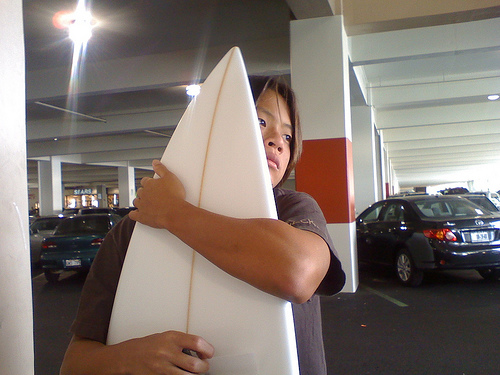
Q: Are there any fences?
A: No, there are no fences.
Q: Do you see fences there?
A: No, there are no fences.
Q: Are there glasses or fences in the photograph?
A: No, there are no fences or glasses.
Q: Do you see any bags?
A: No, there are no bags.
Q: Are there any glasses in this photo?
A: No, there are no glasses.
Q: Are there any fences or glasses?
A: No, there are no glasses or fences.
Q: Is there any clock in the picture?
A: No, there are no clocks.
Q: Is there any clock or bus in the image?
A: No, there are no clocks or buses.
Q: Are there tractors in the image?
A: No, there are no tractors.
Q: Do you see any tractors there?
A: No, there are no tractors.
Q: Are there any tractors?
A: No, there are no tractors.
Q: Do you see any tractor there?
A: No, there are no tractors.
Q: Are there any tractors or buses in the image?
A: No, there are no tractors or buses.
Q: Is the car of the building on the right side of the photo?
A: Yes, the car is on the right of the image.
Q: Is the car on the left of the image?
A: No, the car is on the right of the image.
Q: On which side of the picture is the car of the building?
A: The car is on the right of the image.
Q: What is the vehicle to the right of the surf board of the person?
A: The vehicle is a car.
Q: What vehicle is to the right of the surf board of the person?
A: The vehicle is a car.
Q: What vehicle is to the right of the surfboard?
A: The vehicle is a car.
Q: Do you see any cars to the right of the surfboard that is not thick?
A: Yes, there is a car to the right of the surfboard.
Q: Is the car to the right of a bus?
A: No, the car is to the right of the surfboard.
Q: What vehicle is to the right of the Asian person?
A: The vehicle is a car.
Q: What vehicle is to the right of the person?
A: The vehicle is a car.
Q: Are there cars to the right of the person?
A: Yes, there is a car to the right of the person.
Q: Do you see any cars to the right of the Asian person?
A: Yes, there is a car to the right of the person.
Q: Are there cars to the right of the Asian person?
A: Yes, there is a car to the right of the person.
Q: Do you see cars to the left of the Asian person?
A: No, the car is to the right of the person.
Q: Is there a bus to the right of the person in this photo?
A: No, there is a car to the right of the person.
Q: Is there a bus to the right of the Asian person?
A: No, there is a car to the right of the person.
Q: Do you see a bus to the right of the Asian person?
A: No, there is a car to the right of the person.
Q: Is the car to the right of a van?
A: No, the car is to the right of the person.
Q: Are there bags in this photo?
A: No, there are no bags.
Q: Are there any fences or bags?
A: No, there are no bags or fences.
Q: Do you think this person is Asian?
A: Yes, the person is asian.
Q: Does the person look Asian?
A: Yes, the person is asian.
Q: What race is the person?
A: The person is asian.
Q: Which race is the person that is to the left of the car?
A: The person is asian.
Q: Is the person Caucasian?
A: No, the person is asian.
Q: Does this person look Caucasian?
A: No, the person is asian.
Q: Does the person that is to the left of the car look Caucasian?
A: No, the person is asian.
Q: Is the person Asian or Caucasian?
A: The person is asian.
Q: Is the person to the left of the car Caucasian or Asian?
A: The person is asian.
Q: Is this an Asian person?
A: Yes, this is an Asian person.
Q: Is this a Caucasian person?
A: No, this is an Asian person.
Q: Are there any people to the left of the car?
A: Yes, there is a person to the left of the car.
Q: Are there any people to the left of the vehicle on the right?
A: Yes, there is a person to the left of the car.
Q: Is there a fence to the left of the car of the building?
A: No, there is a person to the left of the car.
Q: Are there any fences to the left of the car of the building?
A: No, there is a person to the left of the car.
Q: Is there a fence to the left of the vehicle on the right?
A: No, there is a person to the left of the car.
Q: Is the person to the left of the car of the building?
A: Yes, the person is to the left of the car.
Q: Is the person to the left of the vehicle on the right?
A: Yes, the person is to the left of the car.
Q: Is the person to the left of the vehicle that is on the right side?
A: Yes, the person is to the left of the car.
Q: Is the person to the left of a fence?
A: No, the person is to the left of the car.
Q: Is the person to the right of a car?
A: No, the person is to the left of a car.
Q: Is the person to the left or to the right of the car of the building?
A: The person is to the left of the car.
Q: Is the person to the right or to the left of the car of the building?
A: The person is to the left of the car.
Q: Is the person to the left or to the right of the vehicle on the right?
A: The person is to the left of the car.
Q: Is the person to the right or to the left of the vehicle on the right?
A: The person is to the left of the car.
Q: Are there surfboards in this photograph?
A: Yes, there is a surfboard.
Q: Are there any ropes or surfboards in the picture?
A: Yes, there is a surfboard.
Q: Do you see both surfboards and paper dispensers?
A: No, there is a surfboard but no paper dispensers.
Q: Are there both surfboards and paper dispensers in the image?
A: No, there is a surfboard but no paper dispensers.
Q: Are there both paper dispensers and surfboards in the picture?
A: No, there is a surfboard but no paper dispensers.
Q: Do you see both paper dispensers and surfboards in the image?
A: No, there is a surfboard but no paper dispensers.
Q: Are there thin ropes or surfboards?
A: Yes, there is a thin surfboard.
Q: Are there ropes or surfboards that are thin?
A: Yes, the surfboard is thin.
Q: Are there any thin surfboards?
A: Yes, there is a thin surfboard.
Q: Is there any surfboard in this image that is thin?
A: Yes, there is a surfboard that is thin.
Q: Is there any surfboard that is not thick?
A: Yes, there is a thin surfboard.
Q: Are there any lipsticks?
A: No, there are no lipsticks.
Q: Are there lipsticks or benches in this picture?
A: No, there are no lipsticks or benches.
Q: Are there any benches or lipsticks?
A: No, there are no lipsticks or benches.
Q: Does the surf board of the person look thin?
A: Yes, the surfboard is thin.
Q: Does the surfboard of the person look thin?
A: Yes, the surfboard is thin.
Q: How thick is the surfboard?
A: The surfboard is thin.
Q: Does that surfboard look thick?
A: No, the surfboard is thin.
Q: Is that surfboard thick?
A: No, the surfboard is thin.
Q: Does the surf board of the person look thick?
A: No, the surfboard is thin.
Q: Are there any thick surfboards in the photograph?
A: No, there is a surfboard but it is thin.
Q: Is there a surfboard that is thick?
A: No, there is a surfboard but it is thin.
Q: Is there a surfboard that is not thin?
A: No, there is a surfboard but it is thin.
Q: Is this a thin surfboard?
A: Yes, this is a thin surfboard.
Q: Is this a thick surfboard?
A: No, this is a thin surfboard.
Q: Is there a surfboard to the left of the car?
A: Yes, there is a surfboard to the left of the car.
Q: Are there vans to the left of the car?
A: No, there is a surfboard to the left of the car.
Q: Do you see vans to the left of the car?
A: No, there is a surfboard to the left of the car.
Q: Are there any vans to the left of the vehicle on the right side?
A: No, there is a surfboard to the left of the car.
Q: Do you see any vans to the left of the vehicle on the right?
A: No, there is a surfboard to the left of the car.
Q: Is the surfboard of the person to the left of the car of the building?
A: Yes, the surfboard is to the left of the car.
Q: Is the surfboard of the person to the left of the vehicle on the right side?
A: Yes, the surfboard is to the left of the car.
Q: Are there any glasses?
A: No, there are no glasses.